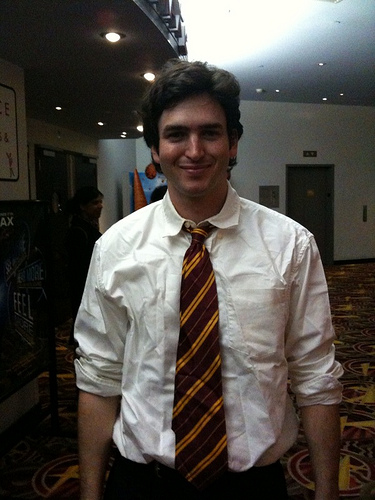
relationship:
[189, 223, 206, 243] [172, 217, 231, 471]
stipe on tie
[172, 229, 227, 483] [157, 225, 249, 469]
stripe on tie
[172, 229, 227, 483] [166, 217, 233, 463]
stripe on tie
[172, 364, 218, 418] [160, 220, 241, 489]
stripe on tie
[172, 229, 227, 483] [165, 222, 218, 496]
stripe on tie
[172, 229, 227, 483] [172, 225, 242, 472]
stripe on tie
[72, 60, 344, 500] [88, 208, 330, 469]
guy in a shirt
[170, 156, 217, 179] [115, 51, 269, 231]
mouth of a man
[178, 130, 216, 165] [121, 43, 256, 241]
nose of a man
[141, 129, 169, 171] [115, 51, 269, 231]
ear of a man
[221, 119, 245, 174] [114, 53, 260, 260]
ear of a man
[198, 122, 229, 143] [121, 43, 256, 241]
eye of a man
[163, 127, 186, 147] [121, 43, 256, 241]
eye of a man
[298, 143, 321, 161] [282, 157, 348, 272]
sign over door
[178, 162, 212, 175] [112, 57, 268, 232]
grin on man's face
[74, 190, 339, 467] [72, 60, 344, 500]
shirt of guy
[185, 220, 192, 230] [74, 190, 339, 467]
button on shirt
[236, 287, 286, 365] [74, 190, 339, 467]
pocket on shirt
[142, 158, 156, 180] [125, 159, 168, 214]
ball on poster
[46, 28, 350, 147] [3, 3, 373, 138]
lights in ceiling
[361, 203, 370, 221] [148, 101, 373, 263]
elevator panel on wall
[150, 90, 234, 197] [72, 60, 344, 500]
head of guy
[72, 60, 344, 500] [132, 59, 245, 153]
guy with hair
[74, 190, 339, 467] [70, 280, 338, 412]
shirt with sleeves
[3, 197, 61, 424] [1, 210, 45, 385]
stand for poster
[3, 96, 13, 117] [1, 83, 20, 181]
e on sign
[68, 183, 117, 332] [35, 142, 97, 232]
woman in front of closed double doors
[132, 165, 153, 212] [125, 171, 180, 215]
cone on advertisement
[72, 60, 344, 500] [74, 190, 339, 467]
guy in a shirt